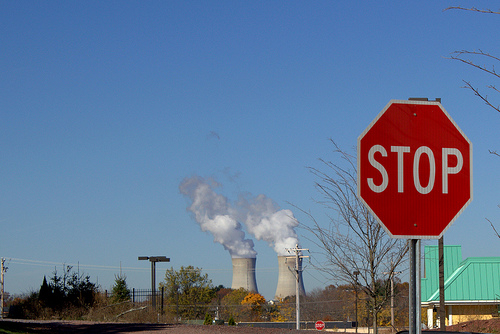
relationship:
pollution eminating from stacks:
[190, 182, 297, 250] [231, 248, 306, 297]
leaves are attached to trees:
[230, 290, 268, 306] [233, 289, 272, 316]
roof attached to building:
[416, 248, 498, 305] [414, 253, 497, 329]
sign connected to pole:
[353, 99, 473, 240] [407, 238, 422, 332]